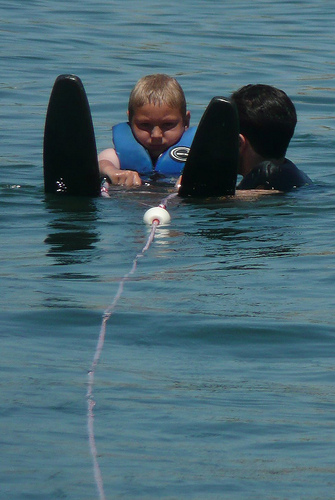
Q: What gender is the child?
A: Male.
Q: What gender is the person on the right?
A: Male.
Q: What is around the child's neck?
A: Life jacket.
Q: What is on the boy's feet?
A: Skis.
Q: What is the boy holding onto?
A: Rope.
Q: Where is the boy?
A: Water.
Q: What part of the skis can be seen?
A: Top half.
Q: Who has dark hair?
A: Man on the right.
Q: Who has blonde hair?
A: Boy.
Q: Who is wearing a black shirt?
A: Man on the right.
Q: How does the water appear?
A: Calm.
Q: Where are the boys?
A: In water.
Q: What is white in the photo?
A: Float.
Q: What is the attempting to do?
A: Water ski.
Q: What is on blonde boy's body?
A: Life preserver.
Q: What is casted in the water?
A: Shadow.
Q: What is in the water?
A: Rope.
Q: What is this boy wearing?
A: Life Vest.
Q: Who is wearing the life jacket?
A: The little boy.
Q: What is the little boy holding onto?
A: The handle with rope.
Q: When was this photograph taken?
A: During the daytime.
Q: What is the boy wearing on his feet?
A: Water skis.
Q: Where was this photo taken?
A: At the lake.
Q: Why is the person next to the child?
A: Giving assistance.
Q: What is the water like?
A: Calm.